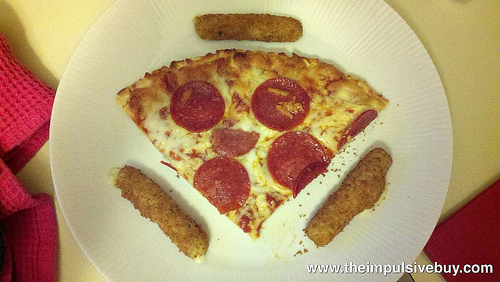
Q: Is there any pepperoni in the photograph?
A: Yes, there is pepperoni.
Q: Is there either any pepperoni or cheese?
A: Yes, there is pepperoni.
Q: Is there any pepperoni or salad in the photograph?
A: Yes, there is pepperoni.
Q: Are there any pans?
A: No, there are no pans.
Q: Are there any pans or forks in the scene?
A: No, there are no pans or forks.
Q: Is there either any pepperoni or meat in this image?
A: Yes, there is pepperoni.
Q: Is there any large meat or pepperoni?
A: Yes, there is large pepperoni.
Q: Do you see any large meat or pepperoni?
A: Yes, there is large pepperoni.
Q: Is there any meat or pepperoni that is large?
A: Yes, the pepperoni is large.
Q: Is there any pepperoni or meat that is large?
A: Yes, the pepperoni is large.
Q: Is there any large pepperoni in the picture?
A: Yes, there is large pepperoni.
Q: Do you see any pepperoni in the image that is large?
A: Yes, there is pepperoni that is large.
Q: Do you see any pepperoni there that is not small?
A: Yes, there is large pepperoni.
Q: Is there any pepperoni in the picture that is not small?
A: Yes, there is large pepperoni.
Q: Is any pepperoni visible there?
A: Yes, there is pepperoni.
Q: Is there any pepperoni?
A: Yes, there is pepperoni.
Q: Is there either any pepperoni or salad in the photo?
A: Yes, there is pepperoni.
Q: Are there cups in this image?
A: No, there are no cups.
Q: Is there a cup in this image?
A: No, there are no cups.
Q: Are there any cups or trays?
A: No, there are no cups or trays.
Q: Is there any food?
A: Yes, there is food.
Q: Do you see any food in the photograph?
A: Yes, there is food.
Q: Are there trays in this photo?
A: No, there are no trays.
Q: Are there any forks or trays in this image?
A: No, there are no trays or forks.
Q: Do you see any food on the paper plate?
A: Yes, there is food on the plate.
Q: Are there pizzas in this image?
A: Yes, there is a pizza.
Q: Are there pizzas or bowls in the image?
A: Yes, there is a pizza.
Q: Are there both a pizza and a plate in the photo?
A: Yes, there are both a pizza and a plate.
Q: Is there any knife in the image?
A: No, there are no knives.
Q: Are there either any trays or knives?
A: No, there are no knives or trays.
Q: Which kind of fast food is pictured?
A: The fast food is a pizza.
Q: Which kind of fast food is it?
A: The food is a pizza.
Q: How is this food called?
A: This is a pizza.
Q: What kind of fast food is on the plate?
A: The food is a pizza.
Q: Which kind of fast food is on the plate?
A: The food is a pizza.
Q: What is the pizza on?
A: The pizza is on the plate.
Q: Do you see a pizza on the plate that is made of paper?
A: Yes, there is a pizza on the plate.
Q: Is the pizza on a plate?
A: Yes, the pizza is on a plate.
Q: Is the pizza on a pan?
A: No, the pizza is on a plate.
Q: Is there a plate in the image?
A: Yes, there is a plate.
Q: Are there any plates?
A: Yes, there is a plate.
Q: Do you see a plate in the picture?
A: Yes, there is a plate.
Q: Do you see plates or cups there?
A: Yes, there is a plate.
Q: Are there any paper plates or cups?
A: Yes, there is a paper plate.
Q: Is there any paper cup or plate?
A: Yes, there is a paper plate.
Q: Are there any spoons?
A: No, there are no spoons.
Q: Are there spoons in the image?
A: No, there are no spoons.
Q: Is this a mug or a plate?
A: This is a plate.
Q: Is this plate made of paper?
A: Yes, the plate is made of paper.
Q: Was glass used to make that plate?
A: No, the plate is made of paper.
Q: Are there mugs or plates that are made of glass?
A: No, there is a plate but it is made of paper.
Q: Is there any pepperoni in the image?
A: Yes, there is pepperoni.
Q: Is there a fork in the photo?
A: No, there are no forks.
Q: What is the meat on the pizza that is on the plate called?
A: The meat is pepperoni.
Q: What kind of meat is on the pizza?
A: The meat is pepperoni.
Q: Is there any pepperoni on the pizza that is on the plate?
A: Yes, there is pepperoni on the pizza.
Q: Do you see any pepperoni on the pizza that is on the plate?
A: Yes, there is pepperoni on the pizza.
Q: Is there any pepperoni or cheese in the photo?
A: Yes, there is pepperoni.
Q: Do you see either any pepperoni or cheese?
A: Yes, there is pepperoni.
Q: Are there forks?
A: No, there are no forks.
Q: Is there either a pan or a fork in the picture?
A: No, there are no forks or pans.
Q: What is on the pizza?
A: The pepperoni is on the pizza.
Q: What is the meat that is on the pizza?
A: The meat is pepperoni.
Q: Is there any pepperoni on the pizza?
A: Yes, there is pepperoni on the pizza.